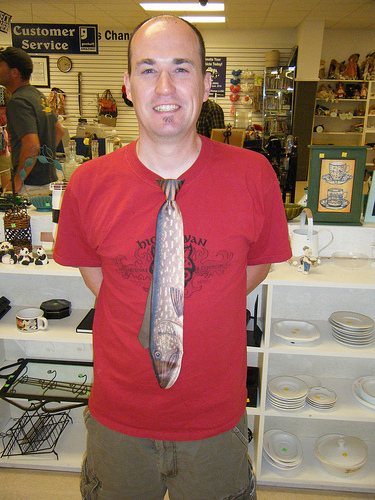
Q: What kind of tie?
A: Fish.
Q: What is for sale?
A: Plates.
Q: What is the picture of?
A: A man.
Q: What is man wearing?
A: A shirt.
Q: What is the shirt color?
A: Red.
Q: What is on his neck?
A: A clip-on tie.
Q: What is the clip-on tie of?
A: A fish.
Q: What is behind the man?
A: Antiques.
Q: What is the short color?
A: Cargo green.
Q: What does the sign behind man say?
A: Customer service.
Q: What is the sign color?
A: Black and white.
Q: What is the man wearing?
A: Red t-shirt, a tie, brown pants.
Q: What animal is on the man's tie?
A: A fish.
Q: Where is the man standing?
A: Behind white shelves.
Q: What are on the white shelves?
A: Plates.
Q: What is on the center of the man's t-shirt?
A: Black logo.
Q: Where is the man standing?
A: In front of a shelf of dishes.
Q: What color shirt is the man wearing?
A: Red.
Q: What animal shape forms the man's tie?
A: A fish.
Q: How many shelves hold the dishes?
A: Three.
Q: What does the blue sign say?
A: Customer service.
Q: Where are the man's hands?
A: Behind his back.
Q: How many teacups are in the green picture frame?
A: Two.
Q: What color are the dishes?
A: White.